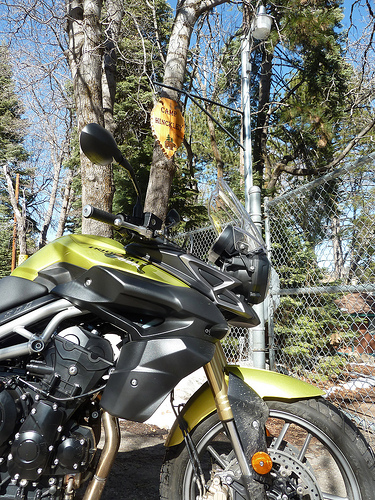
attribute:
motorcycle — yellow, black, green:
[1, 122, 374, 499]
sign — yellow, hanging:
[145, 91, 188, 164]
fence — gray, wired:
[187, 165, 373, 381]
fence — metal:
[167, 151, 374, 441]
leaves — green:
[268, 6, 351, 181]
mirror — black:
[80, 122, 144, 198]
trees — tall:
[63, 1, 117, 243]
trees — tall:
[134, 0, 240, 236]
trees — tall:
[248, 1, 342, 239]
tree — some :
[248, 31, 287, 195]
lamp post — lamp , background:
[243, 9, 281, 369]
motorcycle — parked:
[155, 142, 374, 450]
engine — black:
[0, 328, 106, 497]